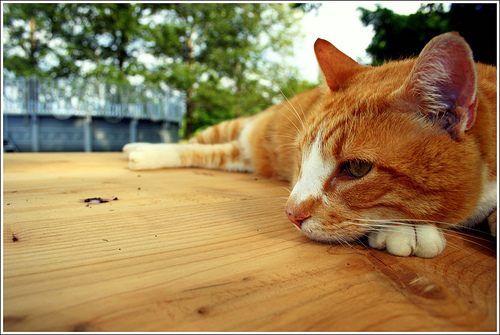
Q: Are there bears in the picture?
A: No, there are no bears.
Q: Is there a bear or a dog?
A: No, there are no bears or dogs.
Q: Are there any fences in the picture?
A: Yes, there is a fence.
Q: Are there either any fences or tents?
A: Yes, there is a fence.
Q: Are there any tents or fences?
A: Yes, there is a fence.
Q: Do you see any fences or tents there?
A: Yes, there is a fence.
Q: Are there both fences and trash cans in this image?
A: No, there is a fence but no trash cans.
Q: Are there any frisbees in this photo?
A: No, there are no frisbees.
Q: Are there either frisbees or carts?
A: No, there are no frisbees or carts.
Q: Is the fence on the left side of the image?
A: Yes, the fence is on the left of the image.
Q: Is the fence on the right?
A: No, the fence is on the left of the image.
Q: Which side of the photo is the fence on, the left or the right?
A: The fence is on the left of the image.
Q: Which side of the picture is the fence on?
A: The fence is on the left of the image.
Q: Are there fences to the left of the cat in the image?
A: Yes, there is a fence to the left of the cat.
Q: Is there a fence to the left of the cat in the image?
A: Yes, there is a fence to the left of the cat.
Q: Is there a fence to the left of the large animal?
A: Yes, there is a fence to the left of the cat.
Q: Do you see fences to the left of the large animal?
A: Yes, there is a fence to the left of the cat.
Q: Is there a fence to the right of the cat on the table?
A: No, the fence is to the left of the cat.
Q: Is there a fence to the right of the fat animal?
A: No, the fence is to the left of the cat.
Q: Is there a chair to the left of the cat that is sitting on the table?
A: No, there is a fence to the left of the cat.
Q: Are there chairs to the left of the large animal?
A: No, there is a fence to the left of the cat.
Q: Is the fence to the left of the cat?
A: Yes, the fence is to the left of the cat.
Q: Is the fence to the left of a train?
A: No, the fence is to the left of the cat.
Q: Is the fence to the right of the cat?
A: No, the fence is to the left of the cat.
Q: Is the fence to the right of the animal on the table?
A: No, the fence is to the left of the cat.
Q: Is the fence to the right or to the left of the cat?
A: The fence is to the left of the cat.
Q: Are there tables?
A: Yes, there is a table.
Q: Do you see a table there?
A: Yes, there is a table.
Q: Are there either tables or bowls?
A: Yes, there is a table.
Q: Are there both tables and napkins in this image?
A: No, there is a table but no napkins.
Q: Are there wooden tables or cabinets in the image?
A: Yes, there is a wood table.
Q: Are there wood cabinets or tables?
A: Yes, there is a wood table.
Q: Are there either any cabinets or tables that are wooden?
A: Yes, the table is wooden.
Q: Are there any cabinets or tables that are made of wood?
A: Yes, the table is made of wood.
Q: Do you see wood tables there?
A: Yes, there is a wood table.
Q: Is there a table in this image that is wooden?
A: Yes, there is a table that is wooden.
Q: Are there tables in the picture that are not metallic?
A: Yes, there is a wooden table.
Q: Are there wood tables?
A: Yes, there is a table that is made of wood.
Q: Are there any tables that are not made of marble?
A: Yes, there is a table that is made of wood.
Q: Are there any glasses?
A: No, there are no glasses.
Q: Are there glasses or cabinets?
A: No, there are no glasses or cabinets.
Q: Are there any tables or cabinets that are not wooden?
A: No, there is a table but it is wooden.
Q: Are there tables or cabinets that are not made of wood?
A: No, there is a table but it is made of wood.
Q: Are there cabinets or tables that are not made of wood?
A: No, there is a table but it is made of wood.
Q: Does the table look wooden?
A: Yes, the table is wooden.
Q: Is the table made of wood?
A: Yes, the table is made of wood.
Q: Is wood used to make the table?
A: Yes, the table is made of wood.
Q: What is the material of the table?
A: The table is made of wood.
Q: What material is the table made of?
A: The table is made of wood.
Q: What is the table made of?
A: The table is made of wood.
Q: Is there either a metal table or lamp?
A: No, there is a table but it is wooden.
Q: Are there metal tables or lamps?
A: No, there is a table but it is wooden.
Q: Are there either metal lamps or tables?
A: No, there is a table but it is wooden.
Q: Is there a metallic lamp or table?
A: No, there is a table but it is wooden.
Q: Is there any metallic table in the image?
A: No, there is a table but it is wooden.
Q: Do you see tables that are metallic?
A: No, there is a table but it is wooden.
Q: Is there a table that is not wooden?
A: No, there is a table but it is wooden.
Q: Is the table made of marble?
A: No, the table is made of wood.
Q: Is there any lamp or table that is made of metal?
A: No, there is a table but it is made of wood.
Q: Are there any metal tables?
A: No, there is a table but it is made of wood.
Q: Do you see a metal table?
A: No, there is a table but it is made of wood.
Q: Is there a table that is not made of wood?
A: No, there is a table but it is made of wood.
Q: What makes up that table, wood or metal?
A: The table is made of wood.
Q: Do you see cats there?
A: Yes, there is a cat.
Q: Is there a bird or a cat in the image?
A: Yes, there is a cat.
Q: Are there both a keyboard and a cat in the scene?
A: No, there is a cat but no keyboards.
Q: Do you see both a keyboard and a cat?
A: No, there is a cat but no keyboards.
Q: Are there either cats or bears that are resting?
A: Yes, the cat is resting.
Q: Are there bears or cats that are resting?
A: Yes, the cat is resting.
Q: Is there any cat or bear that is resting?
A: Yes, the cat is resting.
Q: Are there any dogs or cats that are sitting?
A: Yes, the cat is sitting.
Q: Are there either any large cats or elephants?
A: Yes, there is a large cat.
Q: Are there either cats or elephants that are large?
A: Yes, the cat is large.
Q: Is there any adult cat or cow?
A: Yes, there is an adult cat.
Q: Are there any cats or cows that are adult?
A: Yes, the cat is adult.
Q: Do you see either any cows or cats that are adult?
A: Yes, the cat is adult.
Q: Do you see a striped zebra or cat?
A: Yes, there is a striped cat.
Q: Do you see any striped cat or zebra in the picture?
A: Yes, there is a striped cat.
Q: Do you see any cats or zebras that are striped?
A: Yes, the cat is striped.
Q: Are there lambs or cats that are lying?
A: Yes, the cat is lying.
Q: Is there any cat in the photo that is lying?
A: Yes, there is a cat that is lying.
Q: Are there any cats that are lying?
A: Yes, there is a cat that is lying.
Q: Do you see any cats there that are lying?
A: Yes, there is a cat that is lying.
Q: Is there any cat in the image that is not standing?
A: Yes, there is a cat that is lying.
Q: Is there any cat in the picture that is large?
A: Yes, there is a large cat.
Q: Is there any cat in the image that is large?
A: Yes, there is a cat that is large.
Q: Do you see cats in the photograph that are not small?
A: Yes, there is a large cat.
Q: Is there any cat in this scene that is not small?
A: Yes, there is a large cat.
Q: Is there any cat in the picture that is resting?
A: Yes, there is a cat that is resting.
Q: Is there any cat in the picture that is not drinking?
A: Yes, there is a cat that is resting.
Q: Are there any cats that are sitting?
A: Yes, there is a cat that is sitting.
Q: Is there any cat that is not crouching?
A: Yes, there is a cat that is sitting.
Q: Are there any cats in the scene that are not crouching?
A: Yes, there is a cat that is sitting.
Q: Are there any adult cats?
A: Yes, there is an adult cat.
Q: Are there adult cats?
A: Yes, there is an adult cat.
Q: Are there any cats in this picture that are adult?
A: Yes, there is a cat that is adult.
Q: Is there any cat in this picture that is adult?
A: Yes, there is a cat that is adult.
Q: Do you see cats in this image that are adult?
A: Yes, there is a cat that is adult.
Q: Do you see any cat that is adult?
A: Yes, there is a cat that is adult.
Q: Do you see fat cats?
A: Yes, there is a fat cat.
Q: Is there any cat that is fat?
A: Yes, there is a cat that is fat.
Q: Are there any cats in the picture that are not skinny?
A: Yes, there is a fat cat.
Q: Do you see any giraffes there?
A: No, there are no giraffes.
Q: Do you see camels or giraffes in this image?
A: No, there are no giraffes or camels.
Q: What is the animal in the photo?
A: The animal is a cat.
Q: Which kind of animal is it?
A: The animal is a cat.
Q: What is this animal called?
A: This is a cat.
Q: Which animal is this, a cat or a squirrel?
A: This is a cat.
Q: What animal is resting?
A: The animal is a cat.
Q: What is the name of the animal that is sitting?
A: The animal is a cat.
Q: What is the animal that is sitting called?
A: The animal is a cat.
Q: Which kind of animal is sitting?
A: The animal is a cat.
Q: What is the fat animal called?
A: The animal is a cat.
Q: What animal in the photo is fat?
A: The animal is a cat.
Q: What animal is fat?
A: The animal is a cat.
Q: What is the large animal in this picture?
A: The animal is a cat.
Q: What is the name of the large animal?
A: The animal is a cat.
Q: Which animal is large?
A: The animal is a cat.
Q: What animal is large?
A: The animal is a cat.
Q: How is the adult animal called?
A: The animal is a cat.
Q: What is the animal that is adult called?
A: The animal is a cat.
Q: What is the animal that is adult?
A: The animal is a cat.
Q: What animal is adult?
A: The animal is a cat.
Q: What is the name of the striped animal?
A: The animal is a cat.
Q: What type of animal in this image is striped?
A: The animal is a cat.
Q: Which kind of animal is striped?
A: The animal is a cat.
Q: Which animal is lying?
A: The animal is a cat.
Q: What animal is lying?
A: The animal is a cat.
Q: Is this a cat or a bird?
A: This is a cat.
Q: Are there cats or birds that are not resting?
A: No, there is a cat but it is resting.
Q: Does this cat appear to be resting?
A: Yes, the cat is resting.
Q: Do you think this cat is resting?
A: Yes, the cat is resting.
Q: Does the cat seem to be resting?
A: Yes, the cat is resting.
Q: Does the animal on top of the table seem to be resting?
A: Yes, the cat is resting.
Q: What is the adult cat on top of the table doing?
A: The cat is resting.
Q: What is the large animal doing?
A: The cat is resting.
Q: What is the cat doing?
A: The cat is resting.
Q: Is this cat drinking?
A: No, the cat is resting.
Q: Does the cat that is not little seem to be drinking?
A: No, the cat is resting.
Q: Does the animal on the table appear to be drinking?
A: No, the cat is resting.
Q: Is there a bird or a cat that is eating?
A: No, there is a cat but it is resting.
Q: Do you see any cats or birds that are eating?
A: No, there is a cat but it is resting.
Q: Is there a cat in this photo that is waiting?
A: No, there is a cat but it is resting.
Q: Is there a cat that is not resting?
A: No, there is a cat but it is resting.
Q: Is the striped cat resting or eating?
A: The cat is resting.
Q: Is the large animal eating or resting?
A: The cat is resting.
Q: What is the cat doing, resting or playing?
A: The cat is resting.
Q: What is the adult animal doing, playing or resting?
A: The cat is resting.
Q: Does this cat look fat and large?
A: Yes, the cat is fat and large.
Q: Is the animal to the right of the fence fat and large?
A: Yes, the cat is fat and large.